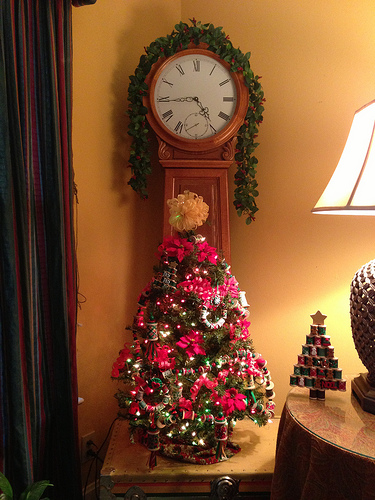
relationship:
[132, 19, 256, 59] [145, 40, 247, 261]
garland over clock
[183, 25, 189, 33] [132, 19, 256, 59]
red flower on garland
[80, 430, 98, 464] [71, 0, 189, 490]
outlet in wall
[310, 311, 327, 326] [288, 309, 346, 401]
star on tree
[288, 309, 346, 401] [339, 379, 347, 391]
tree made of spools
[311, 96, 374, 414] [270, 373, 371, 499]
lamp on table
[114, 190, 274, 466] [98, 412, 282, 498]
christmas tree on trunk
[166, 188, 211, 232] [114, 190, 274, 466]
bow on christmas tree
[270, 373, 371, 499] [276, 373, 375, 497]
table has table cloth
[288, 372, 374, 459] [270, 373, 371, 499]
glass on table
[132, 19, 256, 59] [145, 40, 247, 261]
garland on clock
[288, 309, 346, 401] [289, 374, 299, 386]
tree made of spools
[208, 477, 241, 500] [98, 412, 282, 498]
latch on trunk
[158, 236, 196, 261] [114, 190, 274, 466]
poinsettia on christmas tree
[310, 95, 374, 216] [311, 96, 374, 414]
shade on lamp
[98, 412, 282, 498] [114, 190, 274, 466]
trunk under christmas tree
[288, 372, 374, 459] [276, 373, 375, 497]
glass over table cloth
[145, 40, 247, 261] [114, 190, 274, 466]
clock behind christmas tree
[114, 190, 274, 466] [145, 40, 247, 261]
christmas tree in front of clock